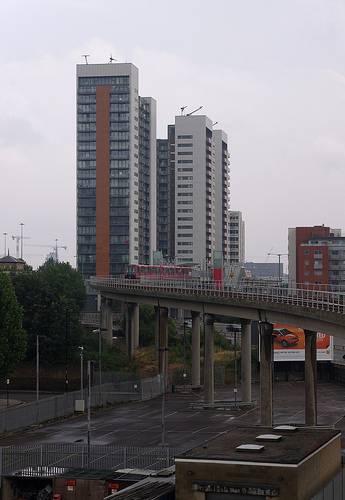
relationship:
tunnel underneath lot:
[4, 467, 59, 497] [12, 403, 221, 489]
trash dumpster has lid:
[3, 465, 70, 498] [5, 463, 65, 481]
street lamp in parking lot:
[69, 345, 188, 490] [47, 363, 268, 495]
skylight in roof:
[235, 439, 262, 455] [182, 422, 341, 465]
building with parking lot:
[135, 422, 342, 497] [46, 393, 256, 475]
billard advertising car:
[257, 321, 334, 363] [274, 324, 298, 345]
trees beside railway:
[5, 255, 125, 371] [142, 283, 345, 316]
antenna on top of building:
[79, 52, 119, 61] [74, 62, 139, 324]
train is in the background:
[122, 260, 196, 280] [10, 5, 333, 284]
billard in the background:
[270, 323, 334, 361] [204, 322, 332, 369]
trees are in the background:
[38, 294, 87, 367] [9, 238, 189, 399]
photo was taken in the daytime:
[2, 5, 333, 493] [5, 5, 334, 492]